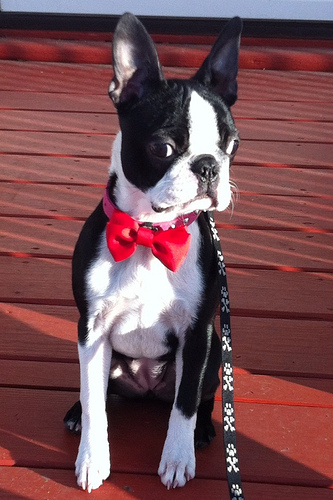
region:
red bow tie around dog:
[95, 175, 252, 276]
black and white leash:
[196, 203, 275, 495]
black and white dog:
[48, 11, 282, 483]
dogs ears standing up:
[96, 6, 263, 112]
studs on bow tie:
[152, 208, 213, 237]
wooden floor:
[0, 57, 332, 496]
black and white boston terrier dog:
[61, 5, 245, 498]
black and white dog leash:
[200, 210, 247, 498]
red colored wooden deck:
[1, 30, 332, 498]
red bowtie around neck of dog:
[103, 206, 196, 274]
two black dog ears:
[103, 1, 244, 109]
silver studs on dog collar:
[166, 214, 195, 230]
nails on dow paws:
[164, 475, 178, 494]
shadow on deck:
[2, 305, 64, 499]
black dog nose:
[188, 150, 222, 185]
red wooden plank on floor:
[0, 465, 331, 498]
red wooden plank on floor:
[1, 385, 331, 485]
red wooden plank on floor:
[0, 357, 332, 408]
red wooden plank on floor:
[0, 300, 331, 380]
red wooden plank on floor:
[0, 254, 332, 318]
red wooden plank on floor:
[1, 214, 332, 273]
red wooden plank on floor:
[1, 59, 331, 102]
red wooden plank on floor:
[2, 91, 331, 122]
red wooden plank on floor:
[2, 108, 331, 141]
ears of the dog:
[93, 6, 250, 108]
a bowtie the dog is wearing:
[102, 205, 192, 274]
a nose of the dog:
[190, 154, 222, 179]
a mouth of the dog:
[149, 183, 231, 221]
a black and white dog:
[64, 6, 249, 496]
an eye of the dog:
[142, 133, 181, 163]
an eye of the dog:
[220, 132, 241, 159]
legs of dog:
[71, 318, 216, 495]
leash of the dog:
[207, 215, 247, 495]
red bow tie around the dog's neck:
[104, 209, 188, 271]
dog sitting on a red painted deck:
[57, 71, 285, 483]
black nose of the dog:
[192, 153, 221, 178]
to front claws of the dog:
[166, 478, 179, 489]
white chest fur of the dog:
[105, 260, 185, 341]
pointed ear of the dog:
[103, 3, 161, 55]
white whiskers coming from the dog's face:
[229, 176, 238, 217]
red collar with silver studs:
[145, 217, 199, 231]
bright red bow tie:
[103, 209, 192, 275]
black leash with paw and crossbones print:
[204, 210, 247, 497]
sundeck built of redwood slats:
[0, 30, 330, 499]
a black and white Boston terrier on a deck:
[64, 11, 240, 488]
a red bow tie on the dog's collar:
[106, 212, 188, 269]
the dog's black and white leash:
[205, 210, 244, 497]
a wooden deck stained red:
[2, 36, 332, 497]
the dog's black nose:
[193, 158, 217, 180]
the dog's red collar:
[103, 178, 201, 227]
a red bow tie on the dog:
[108, 192, 192, 289]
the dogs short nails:
[151, 460, 198, 494]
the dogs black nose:
[194, 152, 224, 183]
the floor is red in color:
[254, 403, 288, 469]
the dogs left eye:
[147, 132, 179, 165]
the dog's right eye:
[217, 122, 248, 163]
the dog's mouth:
[169, 180, 217, 215]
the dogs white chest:
[98, 273, 203, 332]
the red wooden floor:
[253, 386, 305, 492]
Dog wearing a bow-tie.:
[62, 10, 245, 493]